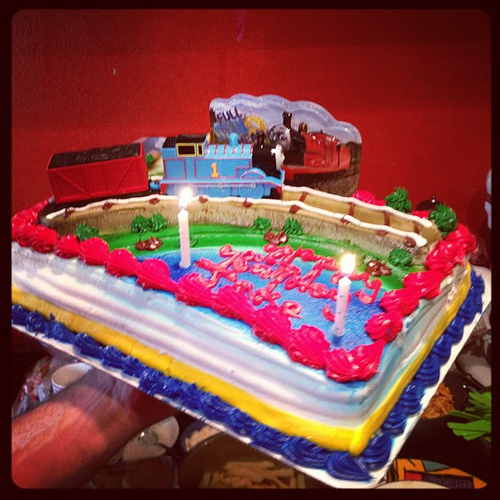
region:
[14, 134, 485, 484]
A CHILD'S BIRTHDAY CAKE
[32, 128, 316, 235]
THOMAS THE TRAIN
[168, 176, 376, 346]
TWO LIT CANDLES ON A BIRTHDAY CAKE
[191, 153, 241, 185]
THE NUMBER 1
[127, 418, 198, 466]
A SPOON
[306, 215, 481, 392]
PINK CAKE ICING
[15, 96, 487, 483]
SOMEONE HOLDING A CAKE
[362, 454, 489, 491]
A PAPER PLATE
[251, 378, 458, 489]
BLUE, YELLOW AND WHITE ICING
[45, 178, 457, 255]
A TRAIN TRACK MAKE OF ICING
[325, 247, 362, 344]
Lit candle on birthday cake.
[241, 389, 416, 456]
Piece of blue yellow and white cake.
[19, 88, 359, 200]
Thomas the train cake decoration.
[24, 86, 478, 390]
Thomas the train birthday cake.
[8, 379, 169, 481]
Mans arm and hand.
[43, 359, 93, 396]
White and blue coffee cup.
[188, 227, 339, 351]
Writing on birthday cake.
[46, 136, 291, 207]
Thomas the train hauling cole.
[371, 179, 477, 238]
Mini green trees made from frosting.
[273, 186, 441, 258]
Railway made from frosting.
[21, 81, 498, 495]
Thomas the train birthday cake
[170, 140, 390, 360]
two lit candles on cake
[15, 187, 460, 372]
pink border icing on cake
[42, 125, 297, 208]
Thomas the train and one red car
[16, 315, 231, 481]
person holding birthday cake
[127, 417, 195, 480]
spoon laying on table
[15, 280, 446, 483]
purple and yellow border on cake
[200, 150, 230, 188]
yellow number one on train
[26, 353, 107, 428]
cup on table beneath cake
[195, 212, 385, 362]
"Happy Birthday Jake" in pink icing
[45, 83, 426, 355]
this looks really good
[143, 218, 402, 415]
yummy looks very tasty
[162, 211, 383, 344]
this are candles on a cake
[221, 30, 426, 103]
this is a red wall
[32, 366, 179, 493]
someones hand carrying a cake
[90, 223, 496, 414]
this is a cake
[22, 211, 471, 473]
this is an indoor photo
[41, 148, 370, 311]
the cake has a train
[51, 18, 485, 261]
this is a colourful image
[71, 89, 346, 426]
i like this picture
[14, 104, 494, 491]
a multicolored birthday cake with candles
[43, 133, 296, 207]
a toy train is on the cake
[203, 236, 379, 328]
writing is on the cake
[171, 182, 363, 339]
two candles are lit on the cake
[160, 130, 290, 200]
the front train is blue in color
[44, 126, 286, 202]
the toy train is pulling a red wagon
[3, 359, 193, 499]
arm is holding up the cake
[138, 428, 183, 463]
a spoon is visible on the table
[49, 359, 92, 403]
part of a cup can be seen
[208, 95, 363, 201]
an illustration is behind the cake